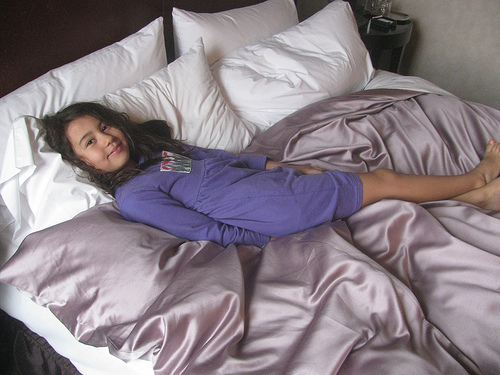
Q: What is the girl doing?
A: Laying on the bed.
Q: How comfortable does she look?
A: Very comfortable.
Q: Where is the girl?
A: Bedroom.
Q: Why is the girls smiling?
A: Because she's comfortable.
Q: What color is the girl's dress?
A: Purple.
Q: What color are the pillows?
A: White.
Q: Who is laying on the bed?
A: A little girl.